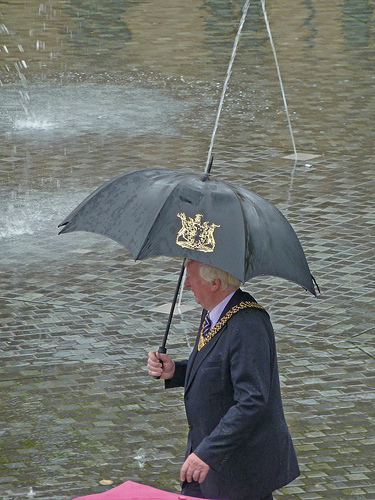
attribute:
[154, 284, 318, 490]
coat — blue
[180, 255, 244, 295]
hair — grey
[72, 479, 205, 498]
object — red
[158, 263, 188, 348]
umbrella stick — thin, black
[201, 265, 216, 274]
hair — gray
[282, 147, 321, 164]
tile — gray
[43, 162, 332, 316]
umbrella — black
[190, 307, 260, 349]
chain — black, gold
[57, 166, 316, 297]
umbrella — black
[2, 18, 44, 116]
rail — falling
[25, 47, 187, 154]
grounds — wet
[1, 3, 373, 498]
walkway — damp, gray, brick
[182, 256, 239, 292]
hair — gray